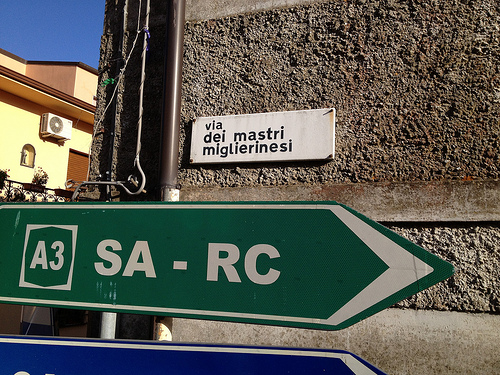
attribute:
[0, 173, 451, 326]
sign — green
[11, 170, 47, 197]
railing — metal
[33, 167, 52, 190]
plant — green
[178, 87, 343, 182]
sign — white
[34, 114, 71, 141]
unit — white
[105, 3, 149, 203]
hook — metal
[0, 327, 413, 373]
sign — blue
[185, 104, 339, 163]
sign — small, white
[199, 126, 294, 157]
letters — black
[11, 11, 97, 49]
sky — blue